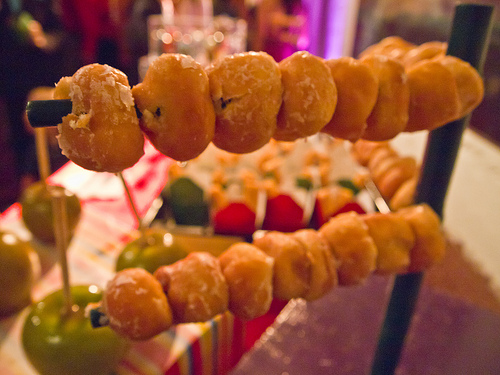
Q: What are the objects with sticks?
A: Apples.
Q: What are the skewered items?
A: Donuts.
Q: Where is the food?
A: At a party.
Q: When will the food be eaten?
A: When people at it.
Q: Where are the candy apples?
A: On a table.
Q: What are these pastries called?
A: Donut holes.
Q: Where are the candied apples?
A: On the table.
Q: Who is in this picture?
A: No one.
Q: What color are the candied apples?
A: Green.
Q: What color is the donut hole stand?
A: Black.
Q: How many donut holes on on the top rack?
A: Eight.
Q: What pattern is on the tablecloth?
A: Striped.